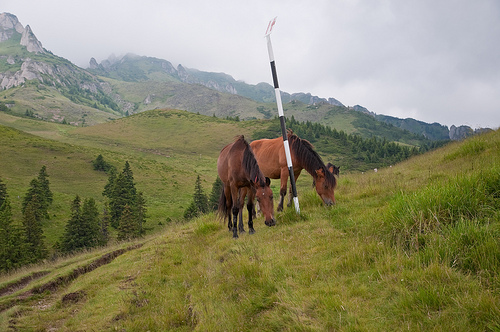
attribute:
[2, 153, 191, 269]
trees — green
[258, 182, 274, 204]
spot — White 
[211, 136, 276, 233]
horse — dark brown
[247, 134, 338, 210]
horse — red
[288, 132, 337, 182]
mane — black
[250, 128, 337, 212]
horse — brown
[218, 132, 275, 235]
horse — brown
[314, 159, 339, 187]
horse — brown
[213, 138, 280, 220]
horse — one of two, dark brown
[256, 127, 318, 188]
horse — one of two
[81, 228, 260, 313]
grass — Green 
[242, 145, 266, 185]
mane — black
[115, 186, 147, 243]
pine tree — green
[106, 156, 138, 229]
pine tree — green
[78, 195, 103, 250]
pine tree — green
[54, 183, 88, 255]
pine tree — green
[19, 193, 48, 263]
pine tree — green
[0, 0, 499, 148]
mountains — rocky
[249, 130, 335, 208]
horse — red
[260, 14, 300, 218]
pole — black, white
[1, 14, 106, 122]
rocky mountain — Distant 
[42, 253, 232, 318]
grass — Green 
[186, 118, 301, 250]
horse — Brown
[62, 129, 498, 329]
green hill — grassy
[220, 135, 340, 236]
horses — together